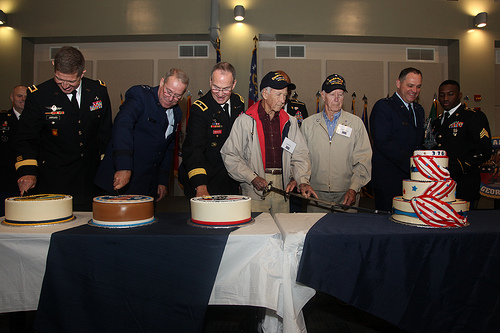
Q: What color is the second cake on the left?
A: Brown.